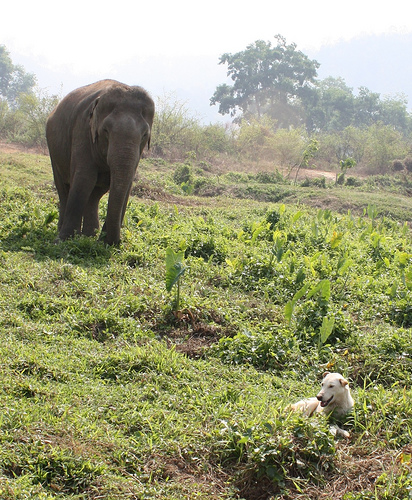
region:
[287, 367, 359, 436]
dog laying in the grass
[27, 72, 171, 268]
elephant is walking in grass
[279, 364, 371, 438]
the dog is brown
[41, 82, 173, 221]
the elephant is brown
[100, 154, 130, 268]
elephant's trunk is down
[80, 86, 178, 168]
elephant's ears are down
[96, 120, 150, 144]
elephant's eyes are black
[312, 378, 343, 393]
dog's eyes are black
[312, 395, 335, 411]
dog's mouth is open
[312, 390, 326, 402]
dog's nose is black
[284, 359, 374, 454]
Dog laying in grass.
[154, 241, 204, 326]
Large green leaf on plant.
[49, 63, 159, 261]
Gray elephant walking on grass.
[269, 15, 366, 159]
Trees in the background.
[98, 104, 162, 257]
Gray trunk on elephant.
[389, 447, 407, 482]
Yellow weeds on the ground.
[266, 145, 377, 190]
Dirt patch on the ground.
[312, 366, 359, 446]
Black nose on dog.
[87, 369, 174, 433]
Green grass on the ground.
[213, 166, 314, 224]
Ditch in the ground.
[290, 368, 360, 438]
dog reclined in vegetation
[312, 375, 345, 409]
head of white dog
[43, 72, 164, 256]
elephant standing in weeds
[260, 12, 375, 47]
cloud cover in sky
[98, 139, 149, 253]
trunk on front of elephant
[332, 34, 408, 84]
hazy trees on horizon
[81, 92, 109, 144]
ear on elephnat head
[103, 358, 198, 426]
green grass on ground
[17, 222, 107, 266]
shadow of elephant on ground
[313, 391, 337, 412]
open mouth on dog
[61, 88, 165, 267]
elephant walks through grass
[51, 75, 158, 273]
elephant behind white dog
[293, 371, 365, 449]
dog lying in grass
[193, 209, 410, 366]
grass is weedy and green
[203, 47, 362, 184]
tall trees in background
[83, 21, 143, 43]
sky is grey and overcast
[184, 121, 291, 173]
tall weeds in background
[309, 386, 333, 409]
dog has brown nose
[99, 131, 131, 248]
elephant has long trunk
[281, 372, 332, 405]
dog has white fur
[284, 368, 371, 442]
white dog laying in grass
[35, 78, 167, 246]
elephant walking through grass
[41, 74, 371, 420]
dog and elephant in the grass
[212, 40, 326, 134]
large tree in background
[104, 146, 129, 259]
trunk of elephant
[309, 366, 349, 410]
face of white dog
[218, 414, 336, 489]
tuft of grass in front of dog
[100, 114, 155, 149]
eyes of elephant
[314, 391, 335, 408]
open mouth of white dog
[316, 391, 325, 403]
black nose of white dog